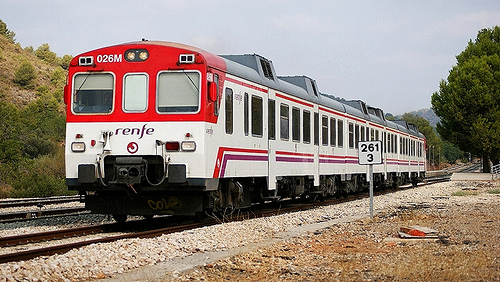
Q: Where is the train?
A: On track.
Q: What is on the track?
A: Train.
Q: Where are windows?
A: On train.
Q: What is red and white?
A: Train.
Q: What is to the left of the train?
A: A grassy hill.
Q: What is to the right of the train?
A: A large tree.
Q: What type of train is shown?
A: A passenger train.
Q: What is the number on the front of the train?
A: 026.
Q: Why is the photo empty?
A: There is noone.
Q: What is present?
A: A train.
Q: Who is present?
A: Nobody.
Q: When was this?
A: Daytime.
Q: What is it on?
A: Rail tracks.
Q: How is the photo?
A: Clear.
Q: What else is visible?
A: Trees.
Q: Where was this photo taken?
A: At a railroad track.